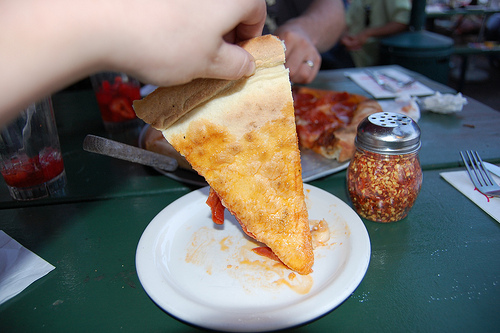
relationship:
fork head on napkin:
[455, 143, 497, 201] [437, 158, 498, 226]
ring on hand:
[303, 59, 312, 69] [265, 21, 323, 81]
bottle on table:
[337, 110, 428, 230] [4, 47, 496, 322]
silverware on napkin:
[357, 63, 414, 94] [338, 60, 456, 100]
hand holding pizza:
[0, 0, 268, 88] [130, 33, 315, 276]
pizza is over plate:
[130, 33, 315, 276] [134, 181, 371, 331]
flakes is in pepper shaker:
[347, 147, 423, 223] [344, 109, 425, 223]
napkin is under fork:
[437, 160, 499, 225] [458, 147, 498, 200]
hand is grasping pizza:
[106, 0, 281, 92] [130, 33, 315, 276]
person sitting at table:
[0, 0, 277, 127] [4, 47, 496, 322]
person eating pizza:
[0, 0, 277, 127] [141, 34, 306, 278]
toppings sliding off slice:
[205, 194, 230, 234] [136, 34, 347, 279]